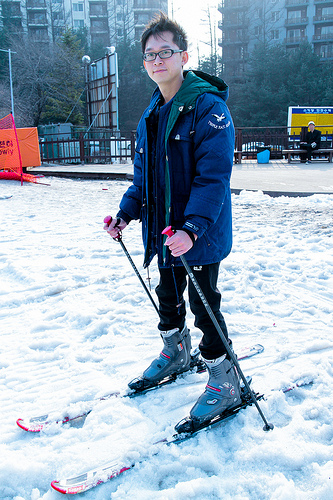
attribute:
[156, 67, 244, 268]
part — jacket's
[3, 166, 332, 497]
snow — white, here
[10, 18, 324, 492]
skater — here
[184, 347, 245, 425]
boot — grey, here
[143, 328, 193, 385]
boot — grey, here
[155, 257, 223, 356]
trouser — here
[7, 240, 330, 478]
lines — here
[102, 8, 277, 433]
man — young, standing, here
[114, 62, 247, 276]
jacket — blue, hooded, heavy, here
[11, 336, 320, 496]
skis — red, white, pair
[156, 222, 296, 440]
stick — here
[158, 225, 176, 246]
handle — red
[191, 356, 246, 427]
shoe — big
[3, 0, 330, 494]
place — full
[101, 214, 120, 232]
handle — red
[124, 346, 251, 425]
boots — grey, ski, pair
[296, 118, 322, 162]
man — sitting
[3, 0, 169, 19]
floor — apartment's, top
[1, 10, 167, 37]
floor — apartment's, top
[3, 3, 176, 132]
building — apartment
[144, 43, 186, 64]
eyeglasses — pair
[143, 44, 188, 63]
frame — black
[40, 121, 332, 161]
fence — brown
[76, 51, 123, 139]
sign — large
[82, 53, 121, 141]
back — sign's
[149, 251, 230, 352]
pants — black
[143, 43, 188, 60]
glasses — black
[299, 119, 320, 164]
person — sitting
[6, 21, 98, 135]
group — leafless, trees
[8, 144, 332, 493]
ground — covered, full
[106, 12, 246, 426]
boy — trying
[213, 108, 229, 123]
bird — white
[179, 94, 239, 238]
arm — jacket's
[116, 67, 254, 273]
coat — blue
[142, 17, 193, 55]
hair — dark